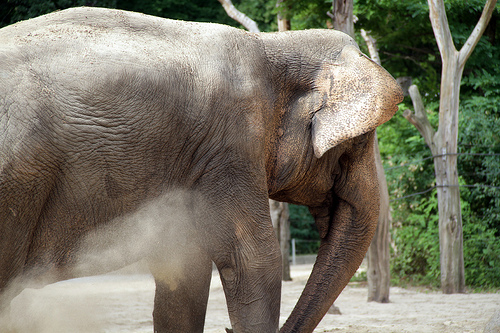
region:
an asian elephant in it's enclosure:
[1, 4, 402, 331]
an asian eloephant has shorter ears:
[311, 41, 406, 163]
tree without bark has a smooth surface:
[413, 6, 489, 297]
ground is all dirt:
[0, 267, 498, 332]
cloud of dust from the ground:
[0, 179, 260, 331]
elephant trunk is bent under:
[274, 152, 394, 332]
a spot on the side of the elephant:
[86, 148, 178, 213]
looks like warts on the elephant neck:
[266, 89, 298, 156]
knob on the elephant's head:
[317, 23, 360, 58]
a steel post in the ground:
[287, 234, 301, 273]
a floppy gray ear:
[314, 57, 405, 152]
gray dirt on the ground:
[352, 303, 474, 325]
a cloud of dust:
[88, 219, 204, 281]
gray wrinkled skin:
[66, 84, 142, 152]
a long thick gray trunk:
[294, 227, 364, 331]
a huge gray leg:
[214, 211, 284, 331]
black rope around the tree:
[436, 148, 486, 198]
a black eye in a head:
[329, 140, 356, 170]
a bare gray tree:
[414, 17, 477, 312]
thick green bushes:
[406, 113, 496, 312]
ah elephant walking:
[12, 7, 416, 323]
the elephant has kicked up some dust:
[7, 191, 285, 316]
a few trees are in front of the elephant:
[223, 3, 498, 302]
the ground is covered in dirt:
[118, 248, 477, 332]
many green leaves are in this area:
[398, 15, 498, 279]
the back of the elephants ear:
[298, 45, 404, 161]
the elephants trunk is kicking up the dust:
[169, 158, 400, 331]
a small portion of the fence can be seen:
[278, 236, 316, 272]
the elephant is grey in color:
[29, 46, 422, 298]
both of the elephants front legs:
[134, 202, 304, 328]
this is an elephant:
[0, 17, 406, 332]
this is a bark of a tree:
[359, 0, 498, 297]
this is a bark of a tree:
[328, 0, 400, 315]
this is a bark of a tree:
[227, 5, 318, 301]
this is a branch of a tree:
[471, 96, 498, 186]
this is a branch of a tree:
[379, 73, 441, 180]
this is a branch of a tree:
[465, 0, 497, 74]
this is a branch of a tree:
[338, 0, 432, 52]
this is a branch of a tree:
[396, 170, 492, 257]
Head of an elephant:
[273, 3, 390, 330]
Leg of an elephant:
[199, 186, 295, 330]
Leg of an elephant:
[144, 185, 232, 331]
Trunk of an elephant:
[284, 162, 378, 325]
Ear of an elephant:
[304, 34, 415, 174]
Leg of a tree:
[423, 9, 475, 326]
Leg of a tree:
[369, 110, 416, 305]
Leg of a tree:
[267, 180, 300, 287]